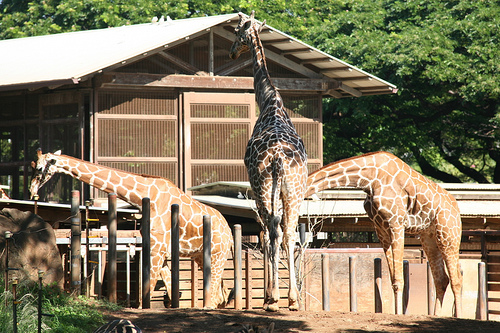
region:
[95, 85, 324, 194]
Brown metal on the side of the building.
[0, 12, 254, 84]
Silver tin roof on building.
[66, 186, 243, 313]
Metal poles in the ground.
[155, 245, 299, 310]
Wooden gate in the background.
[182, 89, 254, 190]
Wire and wood door on building.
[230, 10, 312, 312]
Giraffe standing in front of building.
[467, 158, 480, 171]
Bird in the tree.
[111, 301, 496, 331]
Dirt covering the ground.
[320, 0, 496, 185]
Trees in the background.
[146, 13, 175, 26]
White birds on the roof.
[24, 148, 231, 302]
a brown and white spotted giraffe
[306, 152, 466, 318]
a brown and white spotted giraffe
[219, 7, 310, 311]
a brown and white spotted giraffe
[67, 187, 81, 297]
a tall wood pole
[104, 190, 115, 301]
a tall wood pole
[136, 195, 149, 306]
a tall wood pole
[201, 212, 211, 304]
a tall wood pole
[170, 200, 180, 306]
a tall wood pole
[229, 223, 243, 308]
a tall wood pole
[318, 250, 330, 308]
a tall wood pole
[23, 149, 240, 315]
The giraffe is standing up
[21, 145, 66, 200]
The head of the giraffe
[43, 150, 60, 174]
The ear of the giraffe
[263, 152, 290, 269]
The tail of the giraffe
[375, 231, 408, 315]
The front legs of the giraffe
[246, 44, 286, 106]
The neck of the giraffe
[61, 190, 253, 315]
The poles planted in the ground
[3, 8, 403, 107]
The roof on top of the building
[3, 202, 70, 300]
The boulder is huge and brown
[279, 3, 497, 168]
The trees are large with green leaves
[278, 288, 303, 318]
part of a hoof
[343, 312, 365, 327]
part of a ground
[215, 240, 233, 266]
part of a thighg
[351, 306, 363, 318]
part of a ground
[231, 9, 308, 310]
The tallest giraffe with it's head up.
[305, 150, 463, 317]
A brown and white giraffe with no visible head.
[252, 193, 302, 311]
Three visible legs on the tallest giraffe.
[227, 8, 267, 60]
Large head of the darkest giraffe.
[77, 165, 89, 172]
brown spot on giraffe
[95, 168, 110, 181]
brown spot on giraffe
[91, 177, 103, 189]
brown spot on giraffe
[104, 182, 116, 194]
brown spot on giraffe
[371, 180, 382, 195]
brown spot on giraffe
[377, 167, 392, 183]
brown spot on giraffe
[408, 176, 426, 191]
brown spot on giraffe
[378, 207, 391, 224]
brown spot on giraffe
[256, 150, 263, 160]
brown spot on giraffe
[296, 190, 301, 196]
brown spot on giraffe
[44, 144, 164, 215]
brown spots on giraffe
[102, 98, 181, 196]
metal door on shed